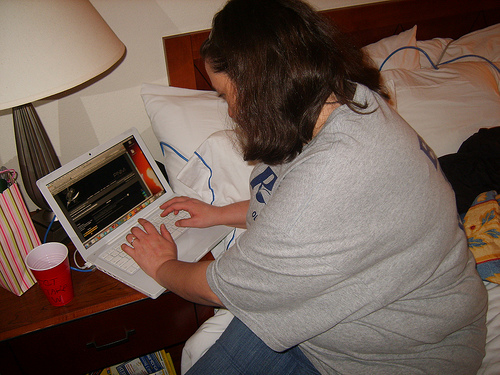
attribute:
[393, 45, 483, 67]
cord — blue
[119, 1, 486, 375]
lady — using computer, sitting, typing, watching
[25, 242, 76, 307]
cup — plastic, red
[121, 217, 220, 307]
hand — typing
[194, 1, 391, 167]
hair — brown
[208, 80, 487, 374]
shirt — gray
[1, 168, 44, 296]
bag — striped, colorful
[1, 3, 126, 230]
lamp — white, large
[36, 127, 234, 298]
laptop — gray, white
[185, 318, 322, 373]
jeans — blue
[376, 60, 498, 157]
pillow — white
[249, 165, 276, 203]
letter — blue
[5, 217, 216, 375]
table — brown